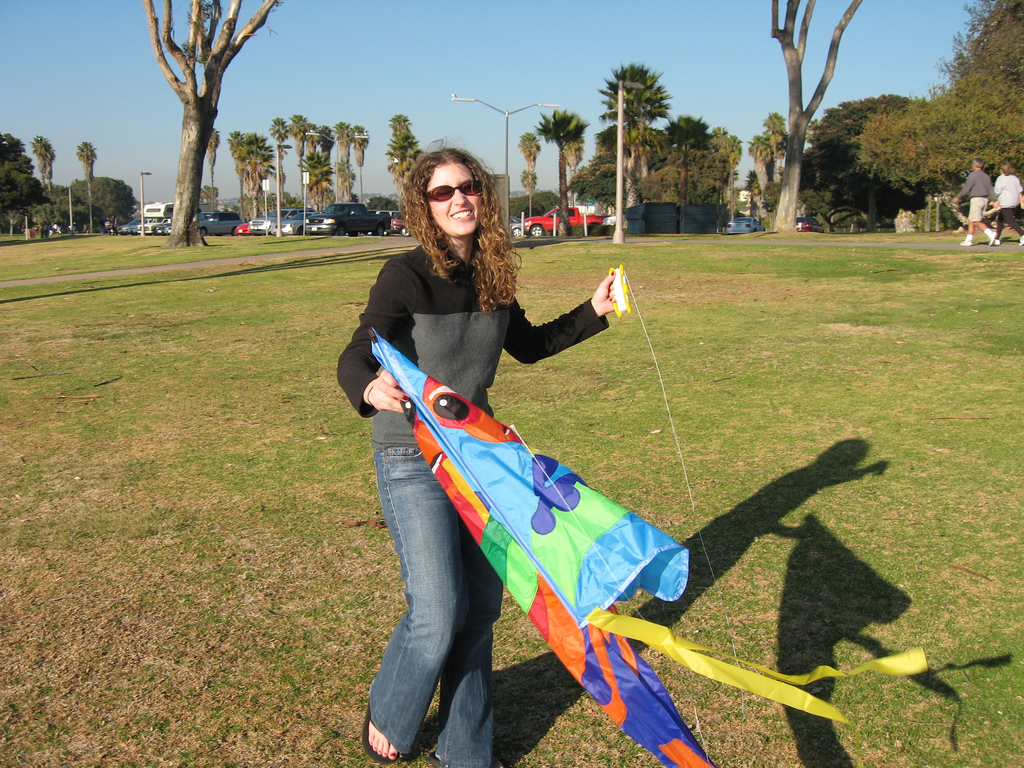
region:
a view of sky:
[430, 21, 536, 102]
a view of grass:
[113, 534, 238, 658]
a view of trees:
[259, 538, 389, 690]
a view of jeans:
[384, 585, 495, 731]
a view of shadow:
[714, 489, 842, 648]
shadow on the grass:
[683, 471, 857, 640]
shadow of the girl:
[721, 442, 870, 648]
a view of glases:
[400, 129, 530, 241]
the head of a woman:
[383, 147, 532, 275]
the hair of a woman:
[378, 191, 437, 258]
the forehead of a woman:
[416, 164, 465, 183]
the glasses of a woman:
[421, 169, 492, 204]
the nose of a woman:
[434, 188, 479, 209]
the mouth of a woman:
[430, 205, 487, 225]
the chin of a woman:
[452, 213, 482, 243]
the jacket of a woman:
[351, 257, 586, 419]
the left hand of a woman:
[586, 245, 651, 323]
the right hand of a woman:
[365, 380, 403, 407]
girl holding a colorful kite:
[334, 146, 715, 766]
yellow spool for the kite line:
[602, 261, 735, 645]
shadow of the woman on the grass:
[694, 424, 952, 764]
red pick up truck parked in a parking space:
[524, 202, 608, 238]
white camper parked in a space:
[133, 198, 172, 237]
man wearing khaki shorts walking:
[947, 155, 1023, 250]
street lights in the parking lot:
[477, 81, 554, 230]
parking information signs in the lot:
[255, 176, 281, 234]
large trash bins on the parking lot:
[618, 193, 737, 236]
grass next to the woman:
[18, 294, 370, 737]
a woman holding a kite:
[337, 154, 900, 766]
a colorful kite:
[369, 332, 832, 750]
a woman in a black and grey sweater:
[351, 151, 623, 708]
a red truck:
[522, 206, 584, 235]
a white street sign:
[258, 180, 275, 219]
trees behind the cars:
[206, 124, 410, 194]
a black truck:
[307, 200, 393, 235]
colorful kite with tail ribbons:
[355, 257, 951, 767]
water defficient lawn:
[3, 237, 1021, 767]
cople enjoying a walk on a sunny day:
[954, 153, 1023, 248]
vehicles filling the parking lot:
[120, 193, 393, 238]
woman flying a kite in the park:
[332, 145, 931, 763]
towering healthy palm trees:
[28, 109, 371, 207]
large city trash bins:
[623, 196, 722, 236]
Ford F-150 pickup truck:
[304, 202, 397, 237]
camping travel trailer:
[136, 202, 175, 238]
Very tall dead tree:
[768, 1, 867, 236]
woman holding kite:
[311, 110, 714, 766]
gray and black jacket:
[324, 253, 609, 449]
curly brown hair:
[399, 123, 526, 317]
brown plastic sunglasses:
[430, 165, 475, 203]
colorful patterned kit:
[356, 315, 846, 767]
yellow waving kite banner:
[583, 613, 931, 744]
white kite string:
[598, 271, 747, 684]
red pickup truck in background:
[516, 198, 614, 240]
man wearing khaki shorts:
[945, 148, 988, 273]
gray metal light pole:
[441, 67, 585, 214]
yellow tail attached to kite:
[582, 602, 928, 730]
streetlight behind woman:
[452, 91, 554, 213]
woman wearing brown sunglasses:
[427, 181, 484, 202]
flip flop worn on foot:
[358, 710, 398, 767]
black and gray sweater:
[330, 244, 618, 419]